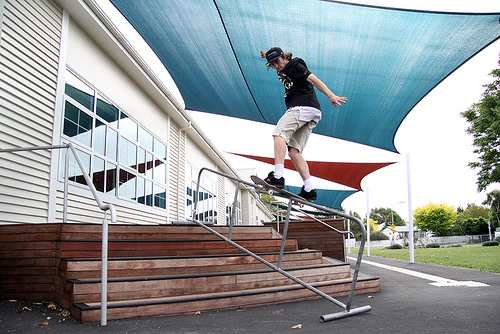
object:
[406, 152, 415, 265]
poles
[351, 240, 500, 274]
grass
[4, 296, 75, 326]
leaves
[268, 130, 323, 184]
muscles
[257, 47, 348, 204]
man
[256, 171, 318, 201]
shoes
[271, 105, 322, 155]
khaki shorts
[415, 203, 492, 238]
tree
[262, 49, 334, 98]
arms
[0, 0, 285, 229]
wall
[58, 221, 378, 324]
staircase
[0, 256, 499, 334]
ground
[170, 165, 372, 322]
rail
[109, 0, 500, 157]
canopy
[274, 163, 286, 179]
sock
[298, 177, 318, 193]
sock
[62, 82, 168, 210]
window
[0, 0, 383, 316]
building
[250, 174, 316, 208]
skateboard